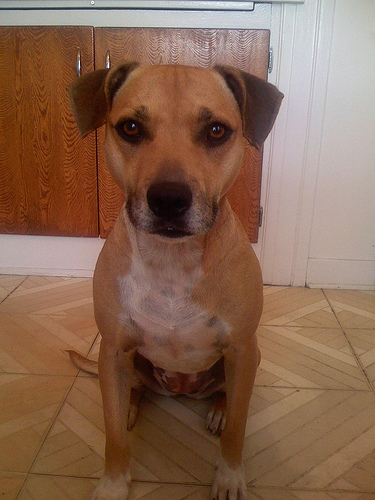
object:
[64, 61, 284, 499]
dog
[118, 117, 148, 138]
eye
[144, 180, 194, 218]
nose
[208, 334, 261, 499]
leg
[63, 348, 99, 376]
tail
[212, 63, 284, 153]
ear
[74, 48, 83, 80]
handle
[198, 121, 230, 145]
eye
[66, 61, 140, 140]
ear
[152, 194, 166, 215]
nostril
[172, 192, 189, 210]
nostril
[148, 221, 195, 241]
mouth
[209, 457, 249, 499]
paws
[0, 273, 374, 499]
floor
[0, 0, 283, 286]
cupboard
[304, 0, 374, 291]
wall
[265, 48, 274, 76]
hinge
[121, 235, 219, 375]
chest